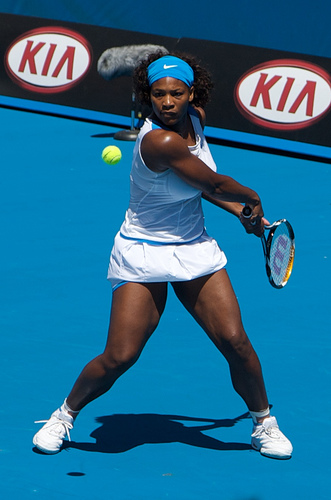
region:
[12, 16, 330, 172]
Kia advertisements on the wall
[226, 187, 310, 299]
Wilson tennis racket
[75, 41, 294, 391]
tennis player preparing to hit the ball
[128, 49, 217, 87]
Nike headband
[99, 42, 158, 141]
furry stool behind the tennis player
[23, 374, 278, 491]
shadow of the tennis player and tennis ball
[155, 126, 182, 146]
light reflection on tennis player's shoulder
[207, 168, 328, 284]
right handed tennis player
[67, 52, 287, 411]
african american tennis player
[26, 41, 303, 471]
tennis player taking her stance to hit the ball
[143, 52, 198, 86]
Blue nike sports headband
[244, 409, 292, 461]
White tennis shoes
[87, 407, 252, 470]
Shadow of woman playing tennis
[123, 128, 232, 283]
White tennis dress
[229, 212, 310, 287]
Black and orange wilson tennis racket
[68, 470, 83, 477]
Shadow of a tennis ball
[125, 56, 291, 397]
Woman swinging a tennis racket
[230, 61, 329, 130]
Advertisement for kia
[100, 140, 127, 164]
Yellow tennis ball with white stripes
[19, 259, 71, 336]
Blue floor of a tennis court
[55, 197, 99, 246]
part of a court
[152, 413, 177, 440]
part of a shade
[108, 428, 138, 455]
edge of a shade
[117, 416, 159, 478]
part of a shade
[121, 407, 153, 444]
part of a shade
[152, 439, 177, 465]
part of a court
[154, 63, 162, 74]
WOMAN IS WEARING A BLUE HEAD BAND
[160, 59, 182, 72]
WHITE NIKE LOGO IS ON THE HEADBAND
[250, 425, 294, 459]
WOMAN IS WEARING WHITE TENNIS SHOES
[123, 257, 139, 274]
LADY IS WEARING A WHITE SKIRT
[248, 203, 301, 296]
WOMAN IS HOLDING A TENNIS RACKET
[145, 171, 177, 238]
LADY IS WEARING A WHITE TANK TOP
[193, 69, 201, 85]
LADY HAIR IS CURLY AND BLACK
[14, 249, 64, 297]
COURTYARD GROUND IS DARK BLUE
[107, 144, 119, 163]
TENNIS BALL IS IN THE AIR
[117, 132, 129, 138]
BASE ON THE STAND IS BLACK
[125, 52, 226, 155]
Woman wearing a blue head band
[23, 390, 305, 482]
Woman wearing white shoes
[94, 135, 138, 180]
Yellow ball in air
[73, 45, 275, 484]
Women standing on blue court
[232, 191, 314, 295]
Black and yellow tennis racket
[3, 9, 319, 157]
Black, red, and white sign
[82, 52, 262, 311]
Women wearing a white dress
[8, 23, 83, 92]
The sign says KIA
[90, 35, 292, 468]
The women is playing tennis